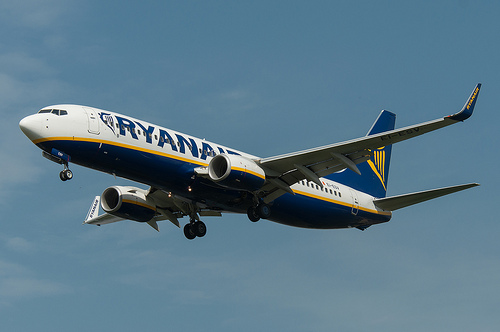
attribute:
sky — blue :
[0, 0, 497, 329]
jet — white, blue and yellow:
[18, 82, 483, 237]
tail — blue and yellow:
[331, 100, 466, 224]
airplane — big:
[14, 77, 484, 243]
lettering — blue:
[88, 90, 275, 211]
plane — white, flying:
[15, 73, 487, 243]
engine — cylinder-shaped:
[191, 152, 268, 187]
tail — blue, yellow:
[338, 88, 395, 201]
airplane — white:
[14, 67, 493, 252]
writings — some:
[105, 112, 214, 157]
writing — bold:
[115, 113, 226, 161]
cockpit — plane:
[25, 90, 90, 148]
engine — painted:
[205, 153, 265, 195]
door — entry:
[83, 107, 99, 136]